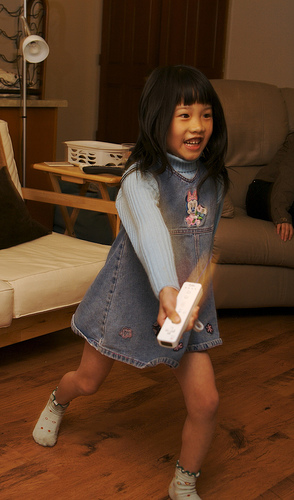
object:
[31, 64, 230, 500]
girl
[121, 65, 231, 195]
hair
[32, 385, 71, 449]
socks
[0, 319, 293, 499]
floor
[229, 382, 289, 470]
wood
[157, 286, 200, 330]
hand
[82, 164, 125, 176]
remote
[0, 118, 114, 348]
seat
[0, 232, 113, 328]
leather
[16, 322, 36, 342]
wood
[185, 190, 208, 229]
mouse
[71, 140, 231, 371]
dress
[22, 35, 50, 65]
light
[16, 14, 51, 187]
lamp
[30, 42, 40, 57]
bulb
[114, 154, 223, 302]
clothing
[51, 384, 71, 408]
trim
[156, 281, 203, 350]
remote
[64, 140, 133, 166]
basket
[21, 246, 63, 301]
white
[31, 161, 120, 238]
table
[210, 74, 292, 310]
sofa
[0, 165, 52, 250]
pillow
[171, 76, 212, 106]
bangs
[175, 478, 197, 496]
ruffles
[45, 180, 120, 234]
fold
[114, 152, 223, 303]
girl sweater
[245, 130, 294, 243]
person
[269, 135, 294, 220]
arm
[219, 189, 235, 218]
blanket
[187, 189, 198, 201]
bow